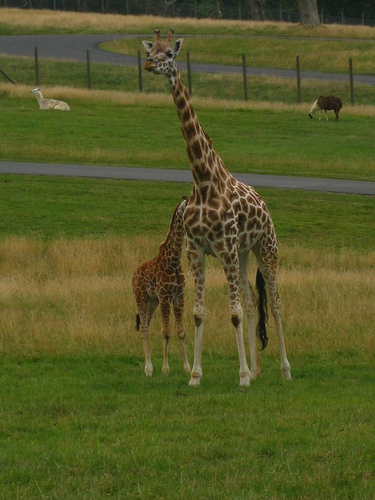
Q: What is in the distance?
A: A curved road.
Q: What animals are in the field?
A: Giraffes.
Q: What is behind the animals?
A: A fence.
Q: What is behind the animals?
A: Dry weeds.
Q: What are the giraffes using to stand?
A: Legs.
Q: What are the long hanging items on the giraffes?
A: Tails.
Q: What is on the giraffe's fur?
A: Spots.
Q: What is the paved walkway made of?
A: Asphalt.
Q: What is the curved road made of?
A: Asphalt.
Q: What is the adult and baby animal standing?
A: Giraffe.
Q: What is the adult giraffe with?
A: A baby giraffe.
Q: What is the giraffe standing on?
A: Grass.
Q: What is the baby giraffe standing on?
A: Grass.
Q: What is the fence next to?
A: A roadway.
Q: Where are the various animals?
A: In a grassy field.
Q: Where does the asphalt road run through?
A: A grassy field.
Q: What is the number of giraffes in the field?
A: Two.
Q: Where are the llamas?
A: The grassy field.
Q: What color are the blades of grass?
A: Green.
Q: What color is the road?
A: Grey.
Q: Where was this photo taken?
A: A zoo.